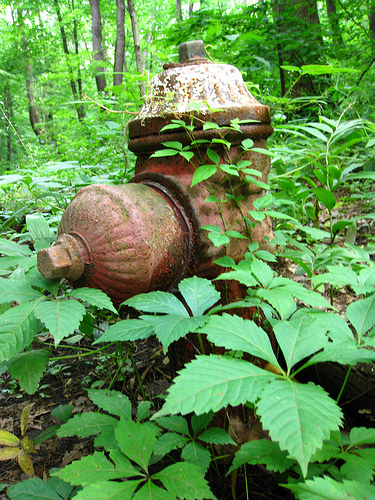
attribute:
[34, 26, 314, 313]
hydrant — old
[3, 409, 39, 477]
leaves — yellow green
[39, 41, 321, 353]
road — decrepit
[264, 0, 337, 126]
tree trunk — large, brown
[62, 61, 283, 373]
hydrant — old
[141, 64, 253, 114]
pant — chipping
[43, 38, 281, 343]
hydrant — rusted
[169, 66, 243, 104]
paint — white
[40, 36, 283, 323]
fire hydrant — old